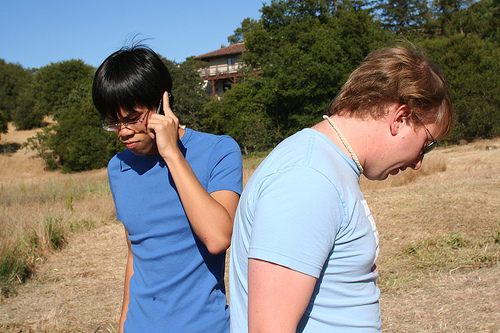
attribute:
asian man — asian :
[90, 32, 244, 331]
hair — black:
[77, 40, 183, 159]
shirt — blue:
[87, 124, 265, 328]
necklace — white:
[305, 103, 374, 173]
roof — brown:
[196, 40, 251, 57]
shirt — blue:
[228, 127, 381, 331]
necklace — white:
[319, 113, 371, 166]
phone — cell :
[151, 91, 176, 131]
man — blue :
[86, 37, 248, 331]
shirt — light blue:
[100, 115, 243, 331]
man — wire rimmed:
[226, 44, 458, 326]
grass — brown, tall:
[441, 164, 471, 193]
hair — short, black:
[87, 40, 177, 109]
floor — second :
[199, 59, 239, 74]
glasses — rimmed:
[94, 107, 155, 132]